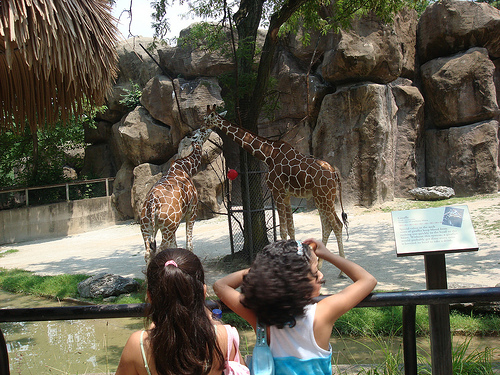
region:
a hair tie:
[163, 255, 178, 266]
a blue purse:
[249, 327, 269, 374]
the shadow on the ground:
[67, 250, 127, 271]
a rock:
[411, 183, 451, 204]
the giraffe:
[208, 113, 351, 240]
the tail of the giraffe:
[148, 212, 160, 249]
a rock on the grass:
[83, 275, 130, 292]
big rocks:
[317, 41, 423, 159]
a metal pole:
[423, 255, 449, 287]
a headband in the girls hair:
[291, 234, 308, 256]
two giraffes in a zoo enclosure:
[0, 0, 497, 284]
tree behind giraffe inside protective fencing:
[205, 0, 352, 259]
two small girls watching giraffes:
[113, 104, 378, 374]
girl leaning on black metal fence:
[214, 234, 377, 374]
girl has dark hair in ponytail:
[113, 245, 248, 374]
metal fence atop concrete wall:
[1, 174, 116, 245]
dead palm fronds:
[0, 0, 121, 136]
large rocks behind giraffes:
[115, 7, 497, 267]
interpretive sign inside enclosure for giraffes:
[137, 103, 478, 271]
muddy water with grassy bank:
[0, 266, 496, 373]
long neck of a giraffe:
[215, 119, 270, 155]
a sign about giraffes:
[390, 204, 478, 256]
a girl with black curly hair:
[242, 242, 316, 327]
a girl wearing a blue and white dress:
[216, 242, 367, 374]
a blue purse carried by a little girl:
[247, 315, 270, 373]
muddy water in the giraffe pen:
[2, 283, 497, 374]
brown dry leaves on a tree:
[1, 0, 121, 126]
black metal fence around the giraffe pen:
[2, 285, 498, 373]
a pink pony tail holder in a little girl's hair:
[163, 256, 179, 271]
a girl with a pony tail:
[116, 249, 246, 374]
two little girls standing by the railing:
[88, 233, 399, 373]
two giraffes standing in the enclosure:
[121, 90, 379, 290]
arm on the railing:
[346, 273, 387, 306]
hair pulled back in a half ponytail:
[143, 247, 230, 373]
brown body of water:
[2, 290, 494, 372]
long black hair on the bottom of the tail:
[341, 213, 355, 243]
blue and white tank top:
[261, 301, 331, 372]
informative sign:
[387, 201, 485, 373]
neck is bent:
[168, 135, 212, 180]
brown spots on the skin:
[202, 105, 352, 280]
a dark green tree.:
[298, 0, 396, 24]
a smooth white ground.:
[51, 231, 105, 266]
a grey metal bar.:
[1, 180, 72, 197]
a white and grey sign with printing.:
[387, 198, 480, 256]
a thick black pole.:
[0, 300, 134, 325]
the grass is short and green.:
[1, 269, 76, 296]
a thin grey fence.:
[234, 186, 266, 243]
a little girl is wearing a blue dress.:
[287, 359, 319, 373]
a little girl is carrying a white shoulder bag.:
[243, 317, 282, 373]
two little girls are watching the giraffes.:
[107, 93, 380, 373]